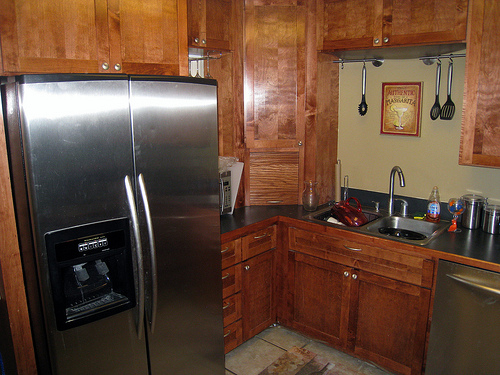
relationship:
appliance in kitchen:
[1, 68, 230, 373] [1, 2, 497, 372]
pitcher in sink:
[330, 192, 368, 228] [306, 195, 445, 258]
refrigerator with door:
[6, 67, 240, 373] [126, 74, 226, 374]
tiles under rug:
[224, 323, 403, 373] [263, 343, 339, 371]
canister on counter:
[456, 189, 486, 236] [443, 232, 498, 261]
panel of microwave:
[219, 168, 234, 215] [217, 152, 243, 221]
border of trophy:
[329, 193, 369, 221] [390, 101, 411, 129]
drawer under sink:
[289, 226, 434, 288] [307, 200, 444, 245]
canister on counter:
[482, 202, 496, 234] [431, 211, 496, 263]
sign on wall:
[380, 85, 419, 138] [322, 69, 497, 219]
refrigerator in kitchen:
[6, 72, 224, 372] [8, 50, 498, 330]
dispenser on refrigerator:
[48, 212, 134, 329] [6, 67, 240, 373]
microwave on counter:
[217, 156, 244, 216] [227, 175, 498, 291]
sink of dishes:
[316, 187, 446, 247] [315, 189, 368, 232]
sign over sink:
[380, 85, 419, 138] [378, 210, 440, 250]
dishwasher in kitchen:
[421, 256, 498, 374] [13, 71, 490, 375]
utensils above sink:
[333, 48, 463, 127] [322, 182, 457, 254]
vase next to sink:
[299, 177, 323, 214] [427, 204, 441, 215]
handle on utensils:
[444, 62, 456, 95] [439, 48, 457, 122]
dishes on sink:
[336, 206, 356, 220] [314, 199, 441, 242]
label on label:
[425, 200, 446, 216] [425, 186, 446, 219]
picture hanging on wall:
[373, 80, 426, 145] [335, 44, 498, 210]